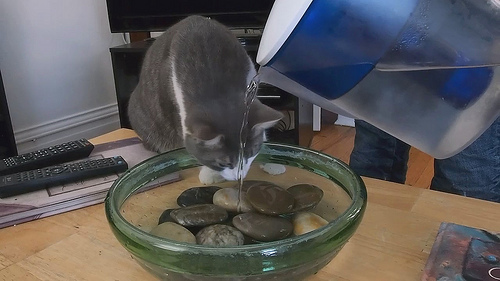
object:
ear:
[246, 98, 284, 132]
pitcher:
[254, 0, 498, 160]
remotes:
[2, 138, 95, 175]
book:
[0, 136, 181, 229]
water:
[235, 56, 500, 213]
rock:
[209, 183, 254, 212]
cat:
[128, 14, 286, 183]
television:
[106, 0, 276, 34]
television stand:
[109, 35, 340, 148]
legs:
[430, 118, 499, 203]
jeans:
[349, 118, 500, 203]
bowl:
[105, 141, 367, 279]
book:
[415, 220, 500, 280]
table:
[0, 128, 498, 281]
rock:
[244, 182, 296, 214]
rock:
[286, 183, 323, 209]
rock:
[176, 185, 222, 207]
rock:
[291, 212, 329, 235]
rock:
[233, 212, 293, 242]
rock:
[147, 221, 200, 246]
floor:
[309, 125, 436, 189]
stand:
[107, 30, 338, 148]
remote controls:
[0, 155, 129, 198]